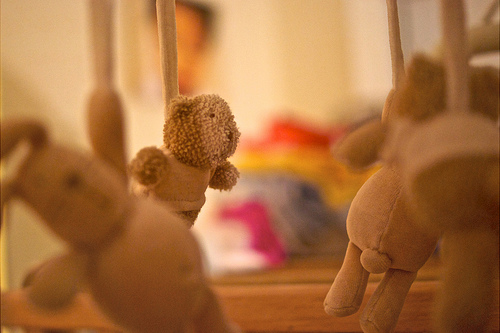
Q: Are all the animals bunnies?
A: No, there are both bunnies and bears.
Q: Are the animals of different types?
A: Yes, they are bunnies and bears.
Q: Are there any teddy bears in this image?
A: Yes, there is a teddy bear.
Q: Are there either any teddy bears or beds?
A: Yes, there is a teddy bear.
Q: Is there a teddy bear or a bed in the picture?
A: Yes, there is a teddy bear.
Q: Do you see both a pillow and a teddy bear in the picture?
A: No, there is a teddy bear but no pillows.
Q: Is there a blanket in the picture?
A: No, there are no blankets.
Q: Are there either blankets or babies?
A: No, there are no blankets or babies.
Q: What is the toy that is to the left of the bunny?
A: The toy is a teddy bear.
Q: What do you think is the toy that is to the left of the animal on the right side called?
A: The toy is a teddy bear.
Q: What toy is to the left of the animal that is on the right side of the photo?
A: The toy is a teddy bear.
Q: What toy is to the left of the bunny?
A: The toy is a teddy bear.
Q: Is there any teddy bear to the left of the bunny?
A: Yes, there is a teddy bear to the left of the bunny.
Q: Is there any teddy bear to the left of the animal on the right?
A: Yes, there is a teddy bear to the left of the bunny.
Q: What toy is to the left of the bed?
A: The toy is a teddy bear.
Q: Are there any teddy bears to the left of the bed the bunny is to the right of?
A: Yes, there is a teddy bear to the left of the bed.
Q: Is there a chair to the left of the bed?
A: No, there is a teddy bear to the left of the bed.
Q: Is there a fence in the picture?
A: No, there are no fences.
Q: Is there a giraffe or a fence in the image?
A: No, there are no fences or giraffes.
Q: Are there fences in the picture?
A: No, there are no fences.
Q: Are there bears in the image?
A: Yes, there are bears.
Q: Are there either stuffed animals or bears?
A: Yes, there are bears.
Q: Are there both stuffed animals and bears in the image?
A: Yes, there are both bears and a stuffed animal.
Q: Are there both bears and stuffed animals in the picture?
A: Yes, there are both bears and a stuffed animal.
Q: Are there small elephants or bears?
A: Yes, there are small bears.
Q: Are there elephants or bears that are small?
A: Yes, the bears are small.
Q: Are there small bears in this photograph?
A: Yes, there are small bears.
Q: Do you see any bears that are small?
A: Yes, there are small bears.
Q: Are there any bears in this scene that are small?
A: Yes, there are bears that are small.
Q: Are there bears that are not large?
A: Yes, there are small bears.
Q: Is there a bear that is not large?
A: Yes, there are small bears.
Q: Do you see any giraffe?
A: No, there are no giraffes.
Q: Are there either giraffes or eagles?
A: No, there are no giraffes or eagles.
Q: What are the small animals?
A: The animals are bears.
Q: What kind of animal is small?
A: The animal is bears.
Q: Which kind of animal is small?
A: The animal is bears.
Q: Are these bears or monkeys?
A: These are bears.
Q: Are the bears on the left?
A: Yes, the bears are on the left of the image.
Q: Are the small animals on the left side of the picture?
A: Yes, the bears are on the left of the image.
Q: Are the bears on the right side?
A: No, the bears are on the left of the image.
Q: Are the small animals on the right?
A: No, the bears are on the left of the image.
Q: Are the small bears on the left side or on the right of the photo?
A: The bears are on the left of the image.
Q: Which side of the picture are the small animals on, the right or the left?
A: The bears are on the left of the image.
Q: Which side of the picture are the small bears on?
A: The bears are on the left of the image.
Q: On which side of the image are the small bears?
A: The bears are on the left of the image.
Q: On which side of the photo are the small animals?
A: The bears are on the left of the image.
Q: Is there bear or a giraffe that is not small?
A: No, there are bears but they are small.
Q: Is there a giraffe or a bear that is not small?
A: No, there are bears but they are small.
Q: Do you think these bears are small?
A: Yes, the bears are small.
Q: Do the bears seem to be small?
A: Yes, the bears are small.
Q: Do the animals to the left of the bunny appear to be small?
A: Yes, the bears are small.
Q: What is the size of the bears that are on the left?
A: The bears are small.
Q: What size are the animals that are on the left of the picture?
A: The bears are small.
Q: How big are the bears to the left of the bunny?
A: The bears are small.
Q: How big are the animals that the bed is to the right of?
A: The bears are small.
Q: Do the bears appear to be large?
A: No, the bears are small.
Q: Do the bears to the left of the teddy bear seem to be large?
A: No, the bears are small.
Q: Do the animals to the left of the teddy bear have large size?
A: No, the bears are small.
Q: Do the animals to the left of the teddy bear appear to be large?
A: No, the bears are small.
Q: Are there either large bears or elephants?
A: No, there are bears but they are small.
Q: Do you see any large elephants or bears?
A: No, there are bears but they are small.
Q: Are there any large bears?
A: No, there are bears but they are small.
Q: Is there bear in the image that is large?
A: No, there are bears but they are small.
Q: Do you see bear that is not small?
A: No, there are bears but they are small.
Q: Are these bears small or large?
A: The bears are small.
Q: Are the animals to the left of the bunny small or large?
A: The bears are small.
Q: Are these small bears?
A: Yes, these are small bears.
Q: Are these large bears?
A: No, these are small bears.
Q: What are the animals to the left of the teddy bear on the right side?
A: The animals are bears.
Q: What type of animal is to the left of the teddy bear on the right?
A: The animals are bears.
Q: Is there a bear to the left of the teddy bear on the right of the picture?
A: Yes, there are bears to the left of the teddy bear.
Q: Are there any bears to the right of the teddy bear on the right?
A: No, the bears are to the left of the teddy bear.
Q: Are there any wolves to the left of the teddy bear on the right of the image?
A: No, there are bears to the left of the teddy bear.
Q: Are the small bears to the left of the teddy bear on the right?
A: Yes, the bears are to the left of the teddy bear.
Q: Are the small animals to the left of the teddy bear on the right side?
A: Yes, the bears are to the left of the teddy bear.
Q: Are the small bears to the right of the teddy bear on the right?
A: No, the bears are to the left of the teddy bear.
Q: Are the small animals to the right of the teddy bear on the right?
A: No, the bears are to the left of the teddy bear.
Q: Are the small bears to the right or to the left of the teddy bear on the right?
A: The bears are to the left of the teddy bear.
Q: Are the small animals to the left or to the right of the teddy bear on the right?
A: The bears are to the left of the teddy bear.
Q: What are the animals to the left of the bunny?
A: The animals are bears.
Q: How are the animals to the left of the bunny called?
A: The animals are bears.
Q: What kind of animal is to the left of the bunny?
A: The animals are bears.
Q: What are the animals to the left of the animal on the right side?
A: The animals are bears.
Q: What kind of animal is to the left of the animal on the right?
A: The animals are bears.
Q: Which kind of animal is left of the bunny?
A: The animals are bears.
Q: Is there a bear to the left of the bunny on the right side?
A: Yes, there are bears to the left of the bunny.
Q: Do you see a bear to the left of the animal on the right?
A: Yes, there are bears to the left of the bunny.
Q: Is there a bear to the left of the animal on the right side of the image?
A: Yes, there are bears to the left of the bunny.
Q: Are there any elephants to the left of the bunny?
A: No, there are bears to the left of the bunny.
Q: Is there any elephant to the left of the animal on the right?
A: No, there are bears to the left of the bunny.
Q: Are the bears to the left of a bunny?
A: Yes, the bears are to the left of a bunny.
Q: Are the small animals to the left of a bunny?
A: Yes, the bears are to the left of a bunny.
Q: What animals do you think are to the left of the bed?
A: The animals are bears.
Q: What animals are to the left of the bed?
A: The animals are bears.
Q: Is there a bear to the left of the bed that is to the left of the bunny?
A: Yes, there are bears to the left of the bed.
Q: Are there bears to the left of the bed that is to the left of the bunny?
A: Yes, there are bears to the left of the bed.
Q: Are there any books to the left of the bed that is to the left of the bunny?
A: No, there are bears to the left of the bed.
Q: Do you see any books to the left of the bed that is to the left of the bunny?
A: No, there are bears to the left of the bed.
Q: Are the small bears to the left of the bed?
A: Yes, the bears are to the left of the bed.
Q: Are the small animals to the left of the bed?
A: Yes, the bears are to the left of the bed.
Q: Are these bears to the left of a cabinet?
A: No, the bears are to the left of the bed.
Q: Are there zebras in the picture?
A: No, there are no zebras.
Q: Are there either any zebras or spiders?
A: No, there are no zebras or spiders.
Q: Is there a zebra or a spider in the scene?
A: No, there are no zebras or spiders.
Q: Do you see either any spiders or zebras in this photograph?
A: No, there are no zebras or spiders.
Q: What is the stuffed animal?
A: The animal is a bunny.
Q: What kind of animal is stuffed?
A: The animal is a bunny.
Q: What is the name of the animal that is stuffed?
A: The animal is a bunny.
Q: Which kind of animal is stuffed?
A: The animal is a bunny.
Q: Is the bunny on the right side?
A: Yes, the bunny is on the right of the image.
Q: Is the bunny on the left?
A: No, the bunny is on the right of the image.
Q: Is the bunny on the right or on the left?
A: The bunny is on the right of the image.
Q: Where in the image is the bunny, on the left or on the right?
A: The bunny is on the right of the image.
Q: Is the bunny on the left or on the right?
A: The bunny is on the right of the image.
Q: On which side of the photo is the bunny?
A: The bunny is on the right of the image.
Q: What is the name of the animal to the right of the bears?
A: The animal is a bunny.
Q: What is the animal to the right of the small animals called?
A: The animal is a bunny.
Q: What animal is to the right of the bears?
A: The animal is a bunny.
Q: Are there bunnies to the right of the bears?
A: Yes, there is a bunny to the right of the bears.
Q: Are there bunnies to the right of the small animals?
A: Yes, there is a bunny to the right of the bears.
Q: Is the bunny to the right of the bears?
A: Yes, the bunny is to the right of the bears.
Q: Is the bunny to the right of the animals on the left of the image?
A: Yes, the bunny is to the right of the bears.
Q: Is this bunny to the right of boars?
A: No, the bunny is to the right of the bears.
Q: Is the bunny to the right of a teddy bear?
A: Yes, the bunny is to the right of a teddy bear.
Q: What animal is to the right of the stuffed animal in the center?
A: The animal is a bunny.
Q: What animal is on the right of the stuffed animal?
A: The animal is a bunny.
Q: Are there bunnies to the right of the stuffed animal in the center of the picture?
A: Yes, there is a bunny to the right of the stuffed animal.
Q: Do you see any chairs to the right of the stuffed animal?
A: No, there is a bunny to the right of the stuffed animal.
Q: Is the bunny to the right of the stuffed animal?
A: Yes, the bunny is to the right of the stuffed animal.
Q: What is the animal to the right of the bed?
A: The animal is a bunny.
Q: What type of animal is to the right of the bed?
A: The animal is a bunny.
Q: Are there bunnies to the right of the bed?
A: Yes, there is a bunny to the right of the bed.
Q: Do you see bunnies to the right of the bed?
A: Yes, there is a bunny to the right of the bed.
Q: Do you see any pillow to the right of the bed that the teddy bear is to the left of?
A: No, there is a bunny to the right of the bed.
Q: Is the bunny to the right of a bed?
A: Yes, the bunny is to the right of a bed.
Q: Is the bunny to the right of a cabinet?
A: No, the bunny is to the right of a bed.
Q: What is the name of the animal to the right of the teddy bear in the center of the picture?
A: The animal is a bunny.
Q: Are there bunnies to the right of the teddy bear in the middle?
A: Yes, there is a bunny to the right of the teddy bear.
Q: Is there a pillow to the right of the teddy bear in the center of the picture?
A: No, there is a bunny to the right of the teddy bear.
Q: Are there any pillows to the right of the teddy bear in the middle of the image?
A: No, there is a bunny to the right of the teddy bear.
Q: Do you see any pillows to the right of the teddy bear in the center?
A: No, there is a bunny to the right of the teddy bear.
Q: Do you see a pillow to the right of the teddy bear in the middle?
A: No, there is a bunny to the right of the teddy bear.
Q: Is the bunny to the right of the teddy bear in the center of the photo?
A: Yes, the bunny is to the right of the teddy bear.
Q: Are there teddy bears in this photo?
A: Yes, there is a teddy bear.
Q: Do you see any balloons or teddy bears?
A: Yes, there is a teddy bear.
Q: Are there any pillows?
A: No, there are no pillows.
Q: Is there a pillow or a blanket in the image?
A: No, there are no pillows or blankets.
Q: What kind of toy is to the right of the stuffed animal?
A: The toy is a teddy bear.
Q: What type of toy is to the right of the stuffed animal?
A: The toy is a teddy bear.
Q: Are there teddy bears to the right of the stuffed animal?
A: Yes, there is a teddy bear to the right of the stuffed animal.